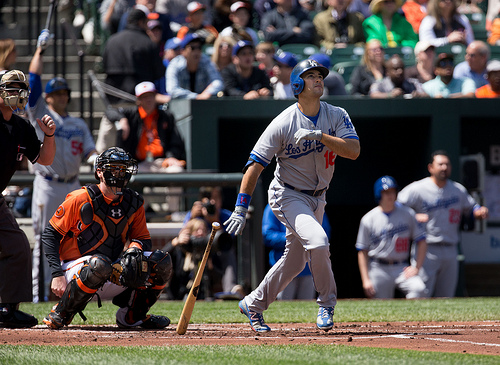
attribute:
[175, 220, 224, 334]
baseball bat — falling, wooden, brown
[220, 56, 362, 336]
batter — looking, playing, running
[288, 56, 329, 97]
helmet — blue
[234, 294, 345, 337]
shoes — aqua blue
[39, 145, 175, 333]
catcher — squatting, playing, crouching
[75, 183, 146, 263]
vest — black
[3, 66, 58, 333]
umpire — watching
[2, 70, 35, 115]
mask — silver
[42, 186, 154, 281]
shirt — orange, black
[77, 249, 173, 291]
knee pads — orange, black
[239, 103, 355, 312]
uniform — gray, blue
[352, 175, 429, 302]
player — playing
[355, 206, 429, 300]
uniform — gray, blue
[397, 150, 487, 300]
player — playing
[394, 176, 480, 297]
uniform — gray, blue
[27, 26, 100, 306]
player — playing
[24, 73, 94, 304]
uniform — gray, blue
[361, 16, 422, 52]
clothes — green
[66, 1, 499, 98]
audience — watching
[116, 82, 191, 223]
coach — sitting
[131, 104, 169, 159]
shirt — orange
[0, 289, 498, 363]
field — green, brown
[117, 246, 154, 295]
mitt — black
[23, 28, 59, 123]
arm — up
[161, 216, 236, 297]
photographer — sitting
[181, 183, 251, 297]
photographer — sitting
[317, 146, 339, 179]
number — red